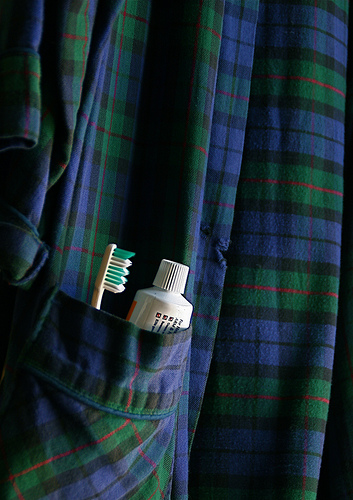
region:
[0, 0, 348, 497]
a warm flannel robe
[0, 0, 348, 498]
a plaid robe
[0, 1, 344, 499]
red lines on the robe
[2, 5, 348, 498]
many thick green lines on a robe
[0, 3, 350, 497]
many dark blue lines on a robe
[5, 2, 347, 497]
many light blue lines on a robe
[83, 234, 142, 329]
a white plastic toothbrush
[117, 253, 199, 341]
a tube of toothpaste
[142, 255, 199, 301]
ridges on a plastic cap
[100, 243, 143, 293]
green bristles on a toothbrush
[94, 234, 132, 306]
blue and white toothbrush bristles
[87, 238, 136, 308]
blue and white toothbrush bristles on white toothbrush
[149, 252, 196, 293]
white cap of toothpaste tube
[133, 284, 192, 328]
red, white and blue toothpaste tube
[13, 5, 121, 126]
blue, green and red plaid robe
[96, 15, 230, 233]
blue, green and red plaid robe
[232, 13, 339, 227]
blue, green and red plaid robe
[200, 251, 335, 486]
blue, green and red plaid robe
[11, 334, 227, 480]
blue, green and red plaid robe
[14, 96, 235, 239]
blue, green and red plaid robe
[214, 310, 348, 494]
PLAID CHECKER PATTERN ON SHIRT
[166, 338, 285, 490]
PLAID CHECKER PATTERN ON SHIRT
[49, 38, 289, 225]
the robe is multi colored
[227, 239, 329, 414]
the robe is plaid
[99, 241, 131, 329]
a toothbrush is in the pocket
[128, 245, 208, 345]
a tube of toothpaste is also in his pocket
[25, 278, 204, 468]
the robe has a pocket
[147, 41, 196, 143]
the background is a black shirt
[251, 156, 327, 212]
the robe has green in it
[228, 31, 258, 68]
this block is blue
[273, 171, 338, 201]
this stripe is red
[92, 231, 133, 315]
the toothbrush has white & green bristles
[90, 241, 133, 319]
toothbrush in a pocket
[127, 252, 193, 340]
toothpaste in a pocket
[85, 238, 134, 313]
the toothbrush has bristles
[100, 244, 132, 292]
the bristles are green and white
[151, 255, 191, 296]
a white toothpaste cap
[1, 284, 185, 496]
a pajama pocket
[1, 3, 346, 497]
the pajamas are plaid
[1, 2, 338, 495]
the pajamas are green and blue and red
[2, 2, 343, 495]
the pajamas are warm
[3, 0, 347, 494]
the pajamas are flannel